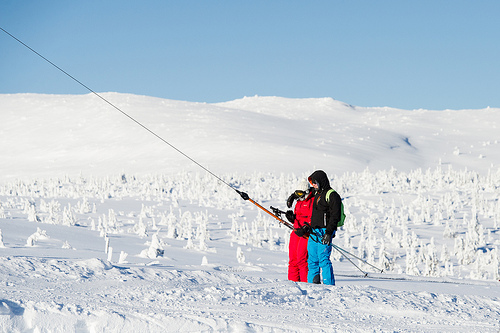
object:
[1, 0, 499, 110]
clouds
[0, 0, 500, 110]
blue sky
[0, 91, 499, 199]
snow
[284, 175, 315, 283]
man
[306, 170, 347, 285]
man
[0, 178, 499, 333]
ground